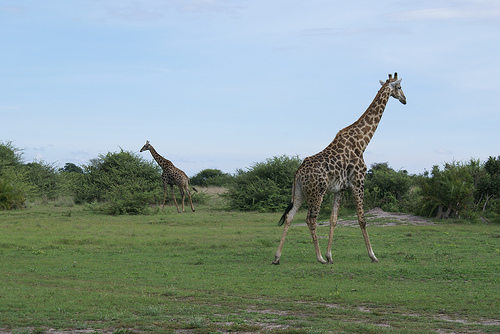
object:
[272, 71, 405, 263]
giraffe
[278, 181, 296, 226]
tail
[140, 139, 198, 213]
giraffe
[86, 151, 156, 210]
bush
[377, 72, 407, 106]
head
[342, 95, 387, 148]
neck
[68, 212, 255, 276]
grass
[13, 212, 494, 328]
ground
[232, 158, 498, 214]
bushes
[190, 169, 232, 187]
clearing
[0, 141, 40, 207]
shrubs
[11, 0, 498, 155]
sky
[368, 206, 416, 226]
dirt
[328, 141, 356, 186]
spots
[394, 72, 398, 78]
ears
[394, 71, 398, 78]
horns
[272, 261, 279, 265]
hooves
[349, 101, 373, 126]
mane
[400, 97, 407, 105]
mouth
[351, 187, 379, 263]
legs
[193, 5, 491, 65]
clouds